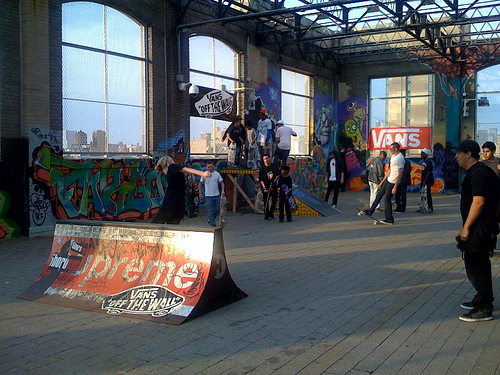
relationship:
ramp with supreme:
[19, 218, 248, 328] [52, 241, 200, 291]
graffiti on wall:
[30, 140, 170, 223] [1, 0, 337, 235]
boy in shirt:
[200, 161, 225, 225] [201, 171, 224, 198]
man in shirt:
[451, 140, 499, 323] [458, 162, 499, 248]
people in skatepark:
[154, 109, 496, 322] [1, 1, 499, 374]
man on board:
[363, 142, 404, 223] [357, 209, 387, 226]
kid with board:
[278, 167, 292, 222] [281, 184, 297, 211]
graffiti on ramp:
[65, 233, 171, 262] [19, 218, 248, 328]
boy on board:
[157, 156, 212, 230] [357, 209, 387, 226]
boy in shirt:
[157, 156, 212, 230] [159, 164, 187, 216]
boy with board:
[157, 156, 212, 230] [357, 209, 387, 226]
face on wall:
[317, 106, 332, 146] [1, 0, 337, 235]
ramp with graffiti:
[19, 218, 248, 328] [65, 233, 171, 262]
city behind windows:
[63, 124, 310, 157] [60, 2, 148, 155]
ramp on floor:
[19, 218, 248, 328] [2, 187, 500, 374]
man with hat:
[451, 140, 499, 323] [450, 140, 483, 161]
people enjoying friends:
[154, 109, 496, 322] [166, 129, 435, 214]